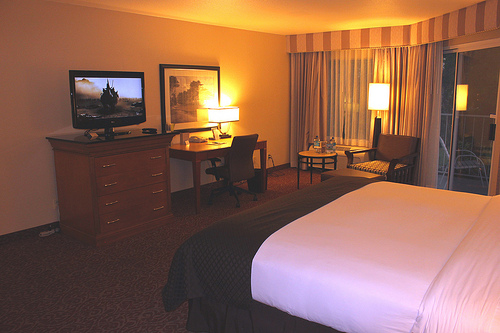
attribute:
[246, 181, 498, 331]
sheets — pink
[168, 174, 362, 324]
blanket — brown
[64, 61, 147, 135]
tv set — flat screen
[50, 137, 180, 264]
dresser — brown, wooden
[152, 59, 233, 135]
frame — brown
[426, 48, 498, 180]
doors — glass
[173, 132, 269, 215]
desk — brown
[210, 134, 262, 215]
chair — brown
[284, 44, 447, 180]
window drapes — sheer, brown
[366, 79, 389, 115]
lamp shade — white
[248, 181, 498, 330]
bedding — white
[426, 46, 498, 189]
sliding door — glass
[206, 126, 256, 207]
desk chair — wheeled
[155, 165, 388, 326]
bedskirt — dark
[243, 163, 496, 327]
sheets — white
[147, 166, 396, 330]
bedspread — brown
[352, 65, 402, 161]
lamp — tall, floor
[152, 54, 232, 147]
picture — large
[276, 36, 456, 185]
curtain — beige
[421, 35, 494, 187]
door — glass, sliding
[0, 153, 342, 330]
floor — nice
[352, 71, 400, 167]
lamp — standing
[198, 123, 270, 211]
chair — here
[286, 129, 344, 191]
endtable — here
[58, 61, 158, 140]
tv — on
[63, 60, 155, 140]
television — on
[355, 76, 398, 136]
lamp — on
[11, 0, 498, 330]
room — dimly lit, inside, motel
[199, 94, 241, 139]
lamp — on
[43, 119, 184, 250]
cabinets — brown, wooden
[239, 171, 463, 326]
spread — white, organized, bed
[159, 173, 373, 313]
sheet — black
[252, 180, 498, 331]
sheet — white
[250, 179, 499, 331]
blanket — white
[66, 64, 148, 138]
television — on, flat screen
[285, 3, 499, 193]
window — sheer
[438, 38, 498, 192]
sliding door — glass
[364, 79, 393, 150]
lamp — on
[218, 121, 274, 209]
chair — desk 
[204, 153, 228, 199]
arms — wooden 